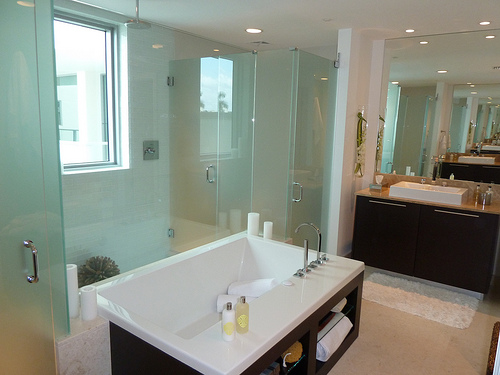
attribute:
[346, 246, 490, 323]
rug — white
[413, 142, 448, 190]
faucet — silver, metal, overhead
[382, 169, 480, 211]
sink — raised, white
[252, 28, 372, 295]
door — glass, shower, green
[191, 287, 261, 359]
bottle — sitting, shampoo, soap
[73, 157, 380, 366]
bathtub — large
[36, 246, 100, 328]
towel — white, rolled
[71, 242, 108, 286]
sponge — yellow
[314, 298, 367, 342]
paper — toilet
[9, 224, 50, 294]
handle — silver, chrome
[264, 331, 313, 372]
shelf — small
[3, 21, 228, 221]
wall — white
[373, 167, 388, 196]
candle — large, white, side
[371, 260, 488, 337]
mat — white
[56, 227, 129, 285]
ball — LOOFAH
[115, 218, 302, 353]
tub — white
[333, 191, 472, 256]
drawer — brown